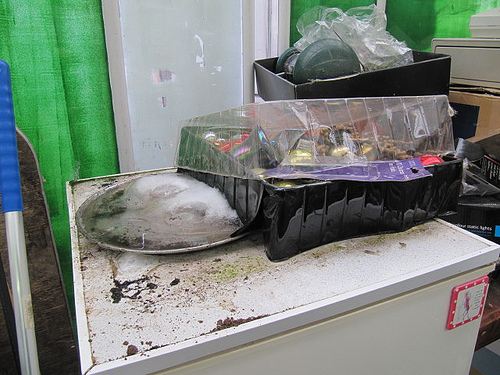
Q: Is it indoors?
A: Yes, it is indoors.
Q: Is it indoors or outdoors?
A: It is indoors.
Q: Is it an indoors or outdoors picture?
A: It is indoors.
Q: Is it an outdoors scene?
A: No, it is indoors.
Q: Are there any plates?
A: Yes, there is a plate.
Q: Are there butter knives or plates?
A: Yes, there is a plate.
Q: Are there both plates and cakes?
A: No, there is a plate but no cakes.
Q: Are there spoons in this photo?
A: No, there are no spoons.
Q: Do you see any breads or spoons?
A: No, there are no spoons or breads.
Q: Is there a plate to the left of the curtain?
A: No, the plate is to the right of the curtain.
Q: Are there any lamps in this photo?
A: No, there are no lamps.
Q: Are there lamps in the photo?
A: No, there are no lamps.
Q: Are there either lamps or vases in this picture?
A: No, there are no lamps or vases.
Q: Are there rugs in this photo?
A: No, there are no rugs.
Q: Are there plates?
A: Yes, there is a plate.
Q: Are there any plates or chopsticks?
A: Yes, there is a plate.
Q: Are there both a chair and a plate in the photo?
A: No, there is a plate but no chairs.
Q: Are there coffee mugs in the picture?
A: No, there are no coffee mugs.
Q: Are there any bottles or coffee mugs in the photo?
A: No, there are no coffee mugs or bottles.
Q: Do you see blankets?
A: No, there are no blankets.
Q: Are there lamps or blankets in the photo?
A: No, there are no blankets or lamps.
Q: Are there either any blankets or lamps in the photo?
A: No, there are no blankets or lamps.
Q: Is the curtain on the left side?
A: Yes, the curtain is on the left of the image.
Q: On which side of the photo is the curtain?
A: The curtain is on the left of the image.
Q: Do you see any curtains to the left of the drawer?
A: Yes, there is a curtain to the left of the drawer.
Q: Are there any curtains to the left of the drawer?
A: Yes, there is a curtain to the left of the drawer.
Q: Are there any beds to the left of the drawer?
A: No, there is a curtain to the left of the drawer.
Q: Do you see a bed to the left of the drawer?
A: No, there is a curtain to the left of the drawer.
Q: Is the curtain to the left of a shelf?
A: No, the curtain is to the left of the drawer.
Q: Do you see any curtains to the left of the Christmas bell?
A: Yes, there is a curtain to the left of the bell.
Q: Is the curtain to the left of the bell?
A: Yes, the curtain is to the left of the bell.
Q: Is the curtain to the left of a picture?
A: No, the curtain is to the left of the bell.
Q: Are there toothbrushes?
A: No, there are no toothbrushes.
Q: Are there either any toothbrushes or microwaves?
A: No, there are no toothbrushes or microwaves.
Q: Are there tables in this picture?
A: Yes, there is a table.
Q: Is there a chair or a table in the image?
A: Yes, there is a table.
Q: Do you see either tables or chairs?
A: Yes, there is a table.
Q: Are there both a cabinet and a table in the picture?
A: No, there is a table but no cabinets.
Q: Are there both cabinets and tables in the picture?
A: No, there is a table but no cabinets.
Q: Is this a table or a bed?
A: This is a table.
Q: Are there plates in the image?
A: Yes, there is a plate.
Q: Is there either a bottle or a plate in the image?
A: Yes, there is a plate.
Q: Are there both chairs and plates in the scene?
A: No, there is a plate but no chairs.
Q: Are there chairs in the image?
A: No, there are no chairs.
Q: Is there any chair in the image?
A: No, there are no chairs.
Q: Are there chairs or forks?
A: No, there are no chairs or forks.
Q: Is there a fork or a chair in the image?
A: No, there are no chairs or forks.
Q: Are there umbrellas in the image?
A: No, there are no umbrellas.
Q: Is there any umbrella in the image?
A: No, there are no umbrellas.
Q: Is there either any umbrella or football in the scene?
A: No, there are no umbrellas or footballs.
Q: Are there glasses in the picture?
A: No, there are no glasses.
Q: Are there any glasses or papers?
A: No, there are no glasses or papers.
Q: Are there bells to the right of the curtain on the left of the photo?
A: Yes, there is a bell to the right of the curtain.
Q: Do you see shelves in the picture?
A: No, there are no shelves.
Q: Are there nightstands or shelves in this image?
A: No, there are no shelves or nightstands.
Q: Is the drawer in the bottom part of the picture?
A: Yes, the drawer is in the bottom of the image.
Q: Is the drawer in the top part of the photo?
A: No, the drawer is in the bottom of the image.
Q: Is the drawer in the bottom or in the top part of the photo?
A: The drawer is in the bottom of the image.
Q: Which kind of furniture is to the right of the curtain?
A: The piece of furniture is a drawer.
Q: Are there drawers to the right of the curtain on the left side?
A: Yes, there is a drawer to the right of the curtain.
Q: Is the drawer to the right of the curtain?
A: Yes, the drawer is to the right of the curtain.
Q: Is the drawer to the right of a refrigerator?
A: No, the drawer is to the right of the curtain.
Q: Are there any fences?
A: No, there are no fences.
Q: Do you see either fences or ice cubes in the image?
A: No, there are no fences or ice cubes.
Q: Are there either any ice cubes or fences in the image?
A: No, there are no fences or ice cubes.